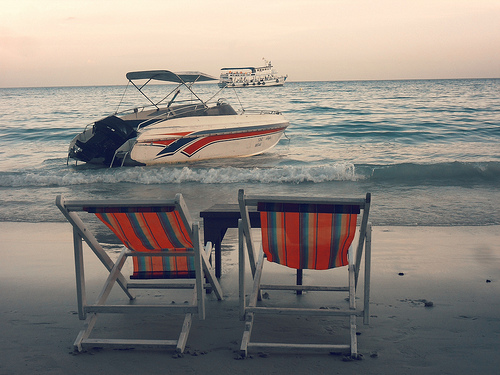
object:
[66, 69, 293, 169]
boat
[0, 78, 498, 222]
water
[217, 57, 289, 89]
boat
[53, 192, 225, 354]
chair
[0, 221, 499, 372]
sand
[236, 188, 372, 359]
chair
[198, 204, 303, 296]
table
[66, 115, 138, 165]
motor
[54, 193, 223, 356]
chair frame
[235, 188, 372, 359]
chair frame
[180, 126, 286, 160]
stripes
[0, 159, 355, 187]
foam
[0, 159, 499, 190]
wave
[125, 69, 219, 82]
canopy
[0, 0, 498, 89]
sky